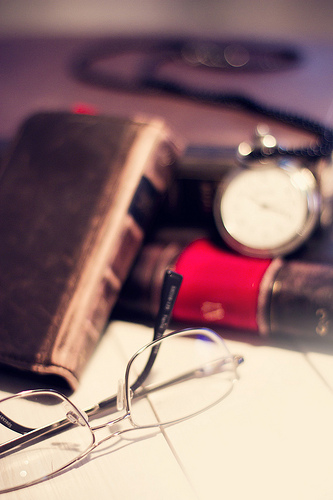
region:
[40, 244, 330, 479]
glasses on the table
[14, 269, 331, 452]
glass that are on a table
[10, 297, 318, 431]
glasses that are upside down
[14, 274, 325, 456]
glasses on a white table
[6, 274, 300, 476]
upside down glasses on a table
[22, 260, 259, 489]
upside down glasses on a white table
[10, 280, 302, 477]
glasses with wire frames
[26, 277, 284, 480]
glasses with thin lenses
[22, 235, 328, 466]
a table wiht glasses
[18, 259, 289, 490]
table with upside glasses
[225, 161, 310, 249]
The watch on the book.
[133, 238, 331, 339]
The black and red bind of the book.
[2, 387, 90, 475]
The left lens of the glasses.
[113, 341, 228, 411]
The right lens of the glasses.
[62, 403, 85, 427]
The left nose piece.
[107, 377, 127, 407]
The right nose piece.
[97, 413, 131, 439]
The nose frame of the glasses.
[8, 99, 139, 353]
The brown book on the left.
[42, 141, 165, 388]
The brown and black bind of the book on the left.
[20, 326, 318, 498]
The beige table the items are on.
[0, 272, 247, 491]
Thin framed reading glasses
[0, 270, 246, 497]
Silver framed reading glasses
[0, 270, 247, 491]
Reading glasses with black rubber tips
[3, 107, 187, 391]
A small leather book cover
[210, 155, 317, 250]
A pocket watch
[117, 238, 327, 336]
A small book lying on its side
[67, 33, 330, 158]
A pocket watch fob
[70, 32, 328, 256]
A pocket watch and fob lying on a table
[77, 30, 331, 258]
A pocket watch and chain lying across a book on a desk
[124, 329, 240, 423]
The lens of a pair of glasses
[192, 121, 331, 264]
a stop watch on a table.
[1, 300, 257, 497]
a pair of glasses on a table.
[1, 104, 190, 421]
a small book on a table.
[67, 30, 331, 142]
a cord on a table top.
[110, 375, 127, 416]
a nose rest on a pair of glasses.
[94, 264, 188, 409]
an ear rest on a pair of glasses.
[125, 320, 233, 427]
a lens on a pair of glasses.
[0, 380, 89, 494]
a left lens in a pair of glasses.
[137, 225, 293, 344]
a section of a red handle.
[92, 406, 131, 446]
a bridge on a pair of glasses.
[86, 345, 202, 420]
this is a spectacle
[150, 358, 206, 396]
this is a glass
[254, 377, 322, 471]
this is a table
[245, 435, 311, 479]
the table is brown in color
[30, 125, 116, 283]
this is a book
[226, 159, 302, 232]
this is a watch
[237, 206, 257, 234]
the watch is white in color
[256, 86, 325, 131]
this is a rope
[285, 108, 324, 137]
the rope is black in color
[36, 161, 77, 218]
the book is brown in color